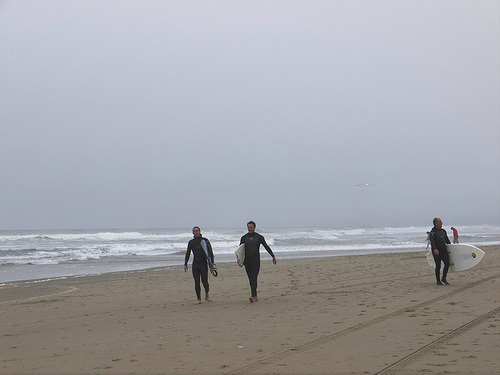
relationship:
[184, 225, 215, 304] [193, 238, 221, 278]
man with a surfboard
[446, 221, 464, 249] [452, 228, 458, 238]
person with a jacket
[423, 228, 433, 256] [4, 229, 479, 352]
person on beach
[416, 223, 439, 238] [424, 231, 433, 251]
head of a person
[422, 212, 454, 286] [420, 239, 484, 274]
man holding surfboard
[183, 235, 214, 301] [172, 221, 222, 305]
suit on man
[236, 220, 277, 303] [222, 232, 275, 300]
man wearing wet suit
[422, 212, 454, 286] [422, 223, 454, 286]
man wearing wet suit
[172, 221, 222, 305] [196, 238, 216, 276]
man carrying surfboard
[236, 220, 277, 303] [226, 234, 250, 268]
man carrying surfboard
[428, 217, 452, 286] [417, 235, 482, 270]
man carrying surfboard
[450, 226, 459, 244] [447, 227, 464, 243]
person wearing jacket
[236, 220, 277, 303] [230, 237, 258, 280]
man carrying surfboard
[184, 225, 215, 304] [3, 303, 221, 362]
man walking beach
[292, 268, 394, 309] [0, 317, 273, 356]
footprints on beach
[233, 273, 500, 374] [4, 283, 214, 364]
tire tracks on beach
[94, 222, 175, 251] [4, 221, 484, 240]
waves crashing background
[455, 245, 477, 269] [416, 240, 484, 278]
emblem on surfboard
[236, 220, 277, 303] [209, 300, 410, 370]
man walking sand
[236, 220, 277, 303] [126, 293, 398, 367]
man walking sand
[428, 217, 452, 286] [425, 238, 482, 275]
man carrying surfboard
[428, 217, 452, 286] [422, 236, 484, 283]
man carrying surfboard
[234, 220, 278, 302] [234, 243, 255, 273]
man carrying surfboard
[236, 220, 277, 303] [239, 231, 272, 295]
man wearing wetsuite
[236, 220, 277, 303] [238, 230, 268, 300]
man wearing wetsuite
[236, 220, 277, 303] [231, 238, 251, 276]
man carrying surfboard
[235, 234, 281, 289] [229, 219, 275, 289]
wetsuit on man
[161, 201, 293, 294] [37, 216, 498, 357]
two men beach beach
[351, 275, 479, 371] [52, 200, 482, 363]
tire tracks on a beach